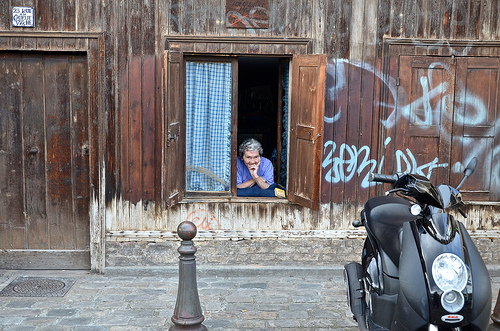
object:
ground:
[101, 267, 355, 327]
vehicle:
[352, 164, 492, 302]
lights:
[427, 245, 469, 315]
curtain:
[183, 59, 235, 195]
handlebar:
[370, 170, 404, 189]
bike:
[345, 159, 493, 328]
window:
[161, 45, 323, 212]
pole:
[151, 208, 241, 320]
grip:
[366, 170, 399, 185]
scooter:
[342, 168, 492, 329]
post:
[154, 214, 209, 329]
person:
[242, 123, 342, 198]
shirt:
[224, 159, 309, 201]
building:
[2, 0, 498, 250]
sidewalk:
[5, 270, 493, 324]